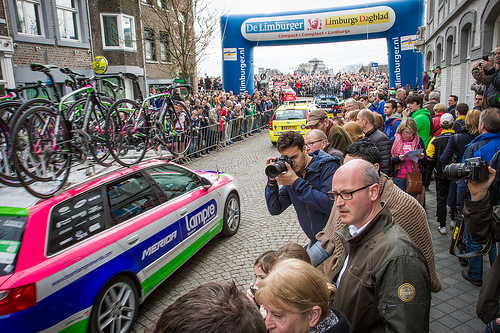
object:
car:
[0, 161, 240, 333]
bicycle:
[0, 63, 195, 200]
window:
[106, 172, 160, 224]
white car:
[0, 152, 241, 333]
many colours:
[0, 157, 243, 333]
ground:
[463, 112, 486, 128]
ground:
[444, 142, 470, 173]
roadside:
[272, 87, 498, 332]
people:
[149, 66, 496, 331]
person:
[252, 257, 355, 333]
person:
[264, 130, 342, 267]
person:
[461, 107, 500, 286]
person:
[426, 112, 457, 236]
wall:
[135, 6, 167, 27]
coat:
[327, 199, 428, 332]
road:
[170, 124, 357, 285]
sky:
[190, 0, 422, 78]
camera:
[265, 155, 294, 178]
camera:
[444, 156, 490, 182]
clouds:
[251, 43, 387, 64]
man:
[329, 159, 431, 333]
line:
[220, 10, 427, 85]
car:
[269, 103, 321, 145]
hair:
[253, 258, 332, 332]